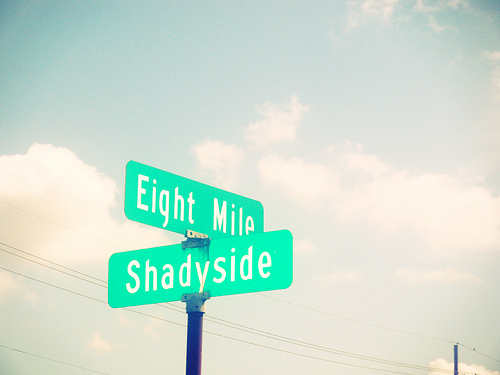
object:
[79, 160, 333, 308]
sign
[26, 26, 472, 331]
sky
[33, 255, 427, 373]
wires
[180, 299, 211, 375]
pole